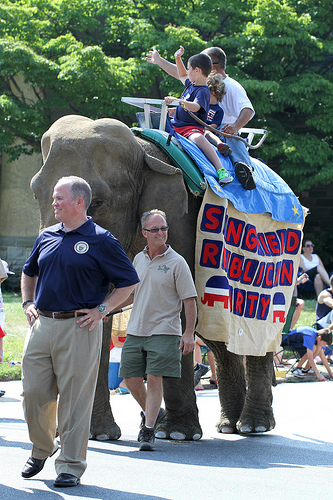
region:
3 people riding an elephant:
[36, 19, 327, 241]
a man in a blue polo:
[13, 166, 128, 440]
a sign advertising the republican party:
[201, 193, 317, 341]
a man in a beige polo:
[129, 209, 189, 388]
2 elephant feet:
[214, 373, 302, 446]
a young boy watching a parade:
[286, 315, 328, 376]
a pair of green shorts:
[122, 334, 197, 388]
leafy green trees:
[7, 10, 131, 99]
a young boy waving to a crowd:
[166, 35, 227, 174]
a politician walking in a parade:
[16, 160, 140, 422]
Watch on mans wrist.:
[97, 301, 109, 316]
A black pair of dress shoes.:
[20, 442, 86, 487]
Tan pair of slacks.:
[18, 302, 106, 476]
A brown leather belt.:
[35, 307, 83, 321]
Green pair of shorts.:
[119, 332, 183, 376]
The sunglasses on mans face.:
[141, 224, 170, 233]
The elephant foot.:
[157, 414, 205, 441]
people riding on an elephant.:
[146, 41, 268, 190]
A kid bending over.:
[284, 326, 332, 385]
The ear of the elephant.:
[139, 148, 189, 220]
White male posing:
[0, 158, 140, 497]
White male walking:
[110, 201, 206, 458]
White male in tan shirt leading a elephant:
[14, 93, 331, 457]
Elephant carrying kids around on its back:
[21, 16, 301, 455]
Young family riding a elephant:
[120, 18, 271, 183]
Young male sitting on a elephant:
[158, 41, 234, 185]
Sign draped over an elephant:
[184, 183, 331, 368]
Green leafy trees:
[11, 5, 331, 123]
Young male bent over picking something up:
[280, 318, 332, 387]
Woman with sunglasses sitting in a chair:
[296, 234, 330, 302]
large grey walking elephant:
[33, 110, 283, 441]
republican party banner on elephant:
[197, 192, 298, 357]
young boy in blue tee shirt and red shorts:
[170, 43, 231, 193]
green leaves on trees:
[264, 44, 303, 113]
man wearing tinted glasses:
[138, 201, 181, 252]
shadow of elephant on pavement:
[107, 426, 332, 467]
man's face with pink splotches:
[47, 173, 93, 229]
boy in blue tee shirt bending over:
[281, 319, 330, 382]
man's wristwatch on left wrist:
[95, 302, 111, 318]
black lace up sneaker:
[134, 419, 160, 453]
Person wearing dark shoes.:
[24, 442, 75, 491]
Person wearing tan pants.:
[44, 395, 93, 438]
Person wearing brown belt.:
[33, 293, 89, 345]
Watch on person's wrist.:
[94, 298, 121, 327]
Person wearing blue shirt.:
[43, 273, 78, 299]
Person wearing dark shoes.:
[137, 431, 172, 470]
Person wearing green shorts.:
[120, 341, 198, 391]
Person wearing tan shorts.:
[146, 301, 164, 318]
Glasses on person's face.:
[140, 221, 191, 251]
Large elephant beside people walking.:
[62, 119, 270, 347]